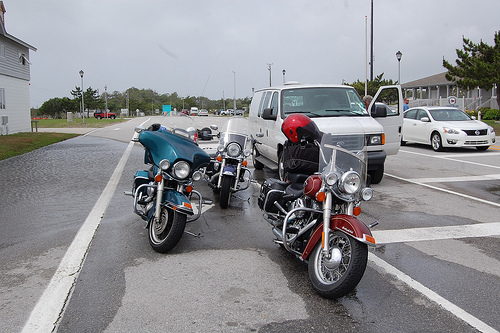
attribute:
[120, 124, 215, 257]
motorcycle — parked, blue, turquoise, red, black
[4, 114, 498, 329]
street — wet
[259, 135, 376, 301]
motorcycle — red, parked, black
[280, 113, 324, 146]
helmet — red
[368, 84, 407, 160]
door — open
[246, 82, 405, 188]
van — white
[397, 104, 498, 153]
car — parked, white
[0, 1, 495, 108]
sky — gray, white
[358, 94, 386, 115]
man — standing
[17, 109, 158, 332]
line — white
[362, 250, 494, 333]
line — white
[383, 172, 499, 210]
line — white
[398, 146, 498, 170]
line — white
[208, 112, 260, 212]
motorcycle — parked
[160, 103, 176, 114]
sign — large, blue gree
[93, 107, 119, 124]
truck — red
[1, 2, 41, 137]
buildig — white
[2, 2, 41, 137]
building — brick, gray, white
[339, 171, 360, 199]
headlight — silver, round